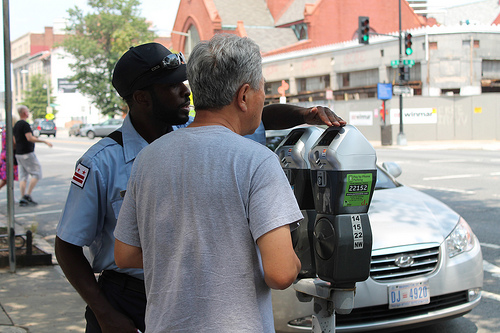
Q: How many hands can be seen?
A: One.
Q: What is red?
A: Rash on baby's face.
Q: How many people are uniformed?
A: One.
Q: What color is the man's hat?
A: Black.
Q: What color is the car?
A: White.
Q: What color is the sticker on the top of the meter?
A: Green.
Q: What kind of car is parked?
A: Hyundai.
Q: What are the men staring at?
A: A parking meter.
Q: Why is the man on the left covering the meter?
A: To see better.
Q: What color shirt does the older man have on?
A: Grey.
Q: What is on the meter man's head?
A: A hat.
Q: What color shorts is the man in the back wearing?
A: Grey.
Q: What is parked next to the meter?
A: A car.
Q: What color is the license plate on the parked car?
A: White.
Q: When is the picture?
A: Daytime.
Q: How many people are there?
A: 3.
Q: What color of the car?
A: Grey.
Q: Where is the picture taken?
A: At parking meters.